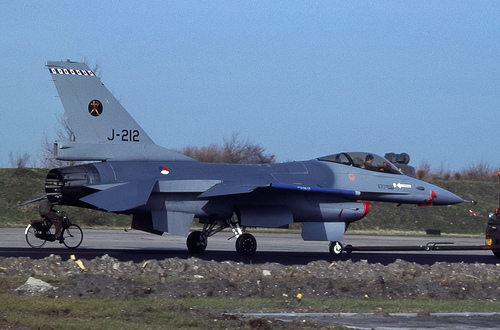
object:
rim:
[243, 234, 256, 250]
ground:
[236, 262, 260, 274]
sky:
[1, 0, 499, 178]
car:
[481, 201, 498, 263]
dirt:
[280, 267, 471, 290]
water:
[192, 259, 342, 309]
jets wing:
[199, 181, 413, 207]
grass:
[50, 303, 175, 315]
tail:
[44, 57, 199, 162]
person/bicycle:
[24, 193, 84, 251]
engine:
[49, 162, 100, 208]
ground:
[97, 265, 213, 325]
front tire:
[60, 221, 84, 251]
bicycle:
[18, 209, 85, 248]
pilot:
[363, 152, 377, 167]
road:
[0, 227, 492, 257]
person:
[42, 193, 67, 247]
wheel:
[328, 242, 343, 258]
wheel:
[234, 233, 258, 258]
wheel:
[186, 230, 208, 255]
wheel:
[23, 220, 50, 248]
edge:
[272, 184, 359, 196]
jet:
[21, 51, 471, 248]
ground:
[280, 297, 439, 327]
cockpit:
[322, 150, 405, 171]